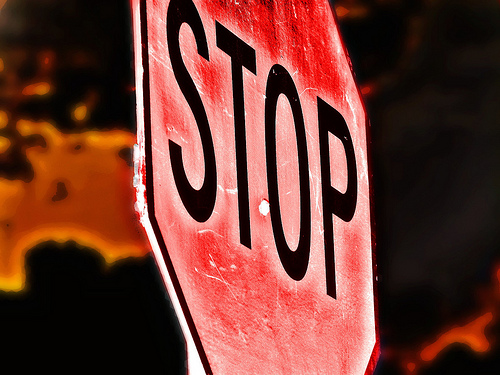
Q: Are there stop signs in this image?
A: Yes, there is a stop sign.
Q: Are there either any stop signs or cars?
A: Yes, there is a stop sign.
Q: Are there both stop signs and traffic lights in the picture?
A: No, there is a stop sign but no traffic lights.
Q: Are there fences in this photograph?
A: No, there are no fences.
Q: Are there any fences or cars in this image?
A: No, there are no fences or cars.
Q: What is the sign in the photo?
A: The sign is a stop sign.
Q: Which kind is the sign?
A: The sign is a stop sign.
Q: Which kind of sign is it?
A: The sign is a stop sign.